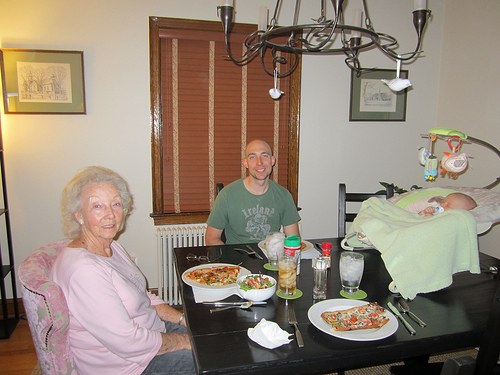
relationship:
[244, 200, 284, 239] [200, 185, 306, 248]
design on shirt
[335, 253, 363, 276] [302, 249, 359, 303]
ice in glass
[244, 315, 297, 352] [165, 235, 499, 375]
napkin on black table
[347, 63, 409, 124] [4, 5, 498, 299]
framed drawing on wall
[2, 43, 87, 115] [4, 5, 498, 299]
framed drawing on wall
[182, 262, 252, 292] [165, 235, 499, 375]
plate on black table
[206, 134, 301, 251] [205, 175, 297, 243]
man in shirt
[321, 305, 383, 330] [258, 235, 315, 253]
pizza in plate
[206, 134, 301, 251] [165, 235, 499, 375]
man at black table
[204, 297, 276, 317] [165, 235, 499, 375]
utensil on black table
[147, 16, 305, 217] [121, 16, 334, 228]
blinds over window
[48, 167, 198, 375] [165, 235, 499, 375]
pink woman sitting at black table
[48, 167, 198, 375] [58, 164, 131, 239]
pink woman has grey hair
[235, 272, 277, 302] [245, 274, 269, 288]
bowl contains salad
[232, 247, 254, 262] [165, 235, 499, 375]
utensil on black table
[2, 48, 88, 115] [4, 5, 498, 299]
framed drawing on wall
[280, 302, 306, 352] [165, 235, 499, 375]
utensil on black table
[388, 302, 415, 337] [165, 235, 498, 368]
utinsil on black table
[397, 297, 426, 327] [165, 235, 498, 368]
spoon on black table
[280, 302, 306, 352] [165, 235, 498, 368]
utensil on black table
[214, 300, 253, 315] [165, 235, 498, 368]
utinsil on black table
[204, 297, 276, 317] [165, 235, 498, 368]
utensil on black table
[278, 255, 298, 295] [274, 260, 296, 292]
glass with beverage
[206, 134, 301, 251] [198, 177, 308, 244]
man in shirt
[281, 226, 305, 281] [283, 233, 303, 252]
bottle has lid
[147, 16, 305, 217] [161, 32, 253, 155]
blinds has blinds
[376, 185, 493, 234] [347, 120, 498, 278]
baby in chair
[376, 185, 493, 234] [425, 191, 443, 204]
baby with paci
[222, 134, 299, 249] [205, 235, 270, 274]
man sitting at table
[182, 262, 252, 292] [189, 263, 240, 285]
plate with food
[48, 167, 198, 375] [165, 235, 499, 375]
pink woman at black table